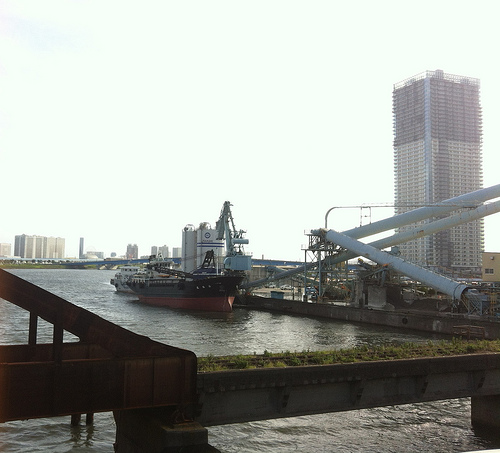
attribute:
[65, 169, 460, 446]
sea port — pictured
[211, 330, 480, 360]
land — grassy 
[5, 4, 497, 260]
sky — OVERCAST 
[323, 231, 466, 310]
white pole — White 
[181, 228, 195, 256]
walls — blue 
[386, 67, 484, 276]
large building — LARGE 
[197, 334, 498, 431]
bridge — OLD 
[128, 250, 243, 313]
ship — LARGE 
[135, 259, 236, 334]
boat — black  , red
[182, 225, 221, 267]
building — round 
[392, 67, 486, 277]
building — round 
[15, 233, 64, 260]
building — round 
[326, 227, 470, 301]
white tubes — white 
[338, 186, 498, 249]
white tubes — white 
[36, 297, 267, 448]
bridge — pictured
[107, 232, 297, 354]
ship — stationary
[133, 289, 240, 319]
bottom — red 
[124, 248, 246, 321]
ship — large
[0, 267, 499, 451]
bridge — pictured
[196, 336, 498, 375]
grass — pictured